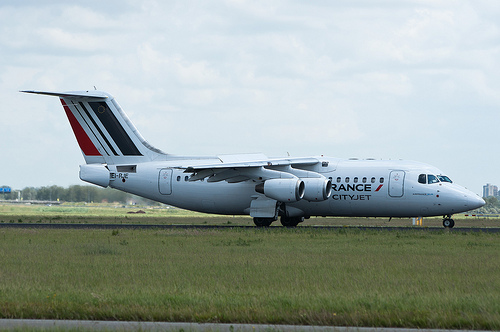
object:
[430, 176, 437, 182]
person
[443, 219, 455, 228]
tire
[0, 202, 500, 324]
grass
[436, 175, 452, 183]
windshield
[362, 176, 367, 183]
window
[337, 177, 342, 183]
window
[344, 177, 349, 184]
window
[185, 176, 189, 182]
window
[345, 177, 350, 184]
window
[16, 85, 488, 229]
airplane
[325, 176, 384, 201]
logo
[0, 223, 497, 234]
tarmac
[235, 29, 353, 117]
clouds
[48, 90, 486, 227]
plan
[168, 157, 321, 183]
wing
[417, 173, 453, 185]
cockpit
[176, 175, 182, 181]
windows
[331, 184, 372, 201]
brand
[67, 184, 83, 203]
trees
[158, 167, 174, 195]
backdoor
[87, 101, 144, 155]
stripe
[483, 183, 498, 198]
building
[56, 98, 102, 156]
red stripe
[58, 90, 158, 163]
fin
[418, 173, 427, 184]
window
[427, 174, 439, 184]
window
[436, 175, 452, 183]
window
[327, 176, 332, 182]
window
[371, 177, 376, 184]
window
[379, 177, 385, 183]
window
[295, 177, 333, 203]
engine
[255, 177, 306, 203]
engine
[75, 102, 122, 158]
stripe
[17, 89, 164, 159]
tail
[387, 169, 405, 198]
door